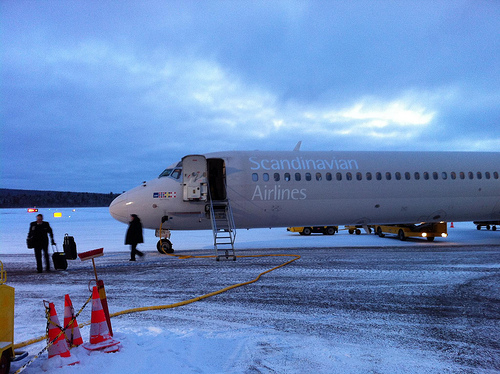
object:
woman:
[123, 211, 145, 261]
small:
[83, 320, 110, 337]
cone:
[80, 284, 122, 352]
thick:
[2, 50, 499, 146]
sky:
[1, 0, 498, 193]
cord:
[13, 221, 301, 349]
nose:
[106, 194, 124, 221]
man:
[25, 212, 56, 275]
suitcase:
[49, 243, 70, 273]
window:
[304, 171, 311, 183]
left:
[0, 178, 122, 374]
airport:
[0, 205, 498, 373]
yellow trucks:
[285, 224, 340, 234]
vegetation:
[0, 187, 117, 208]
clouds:
[0, 0, 499, 194]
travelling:
[24, 214, 70, 272]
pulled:
[49, 238, 68, 272]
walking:
[122, 212, 147, 263]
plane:
[105, 149, 499, 264]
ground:
[0, 205, 499, 374]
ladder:
[206, 200, 237, 263]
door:
[203, 156, 229, 203]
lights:
[418, 230, 428, 239]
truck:
[372, 220, 448, 240]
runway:
[0, 206, 499, 373]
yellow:
[91, 311, 105, 321]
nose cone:
[106, 193, 133, 224]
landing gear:
[153, 229, 173, 255]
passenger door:
[178, 152, 208, 203]